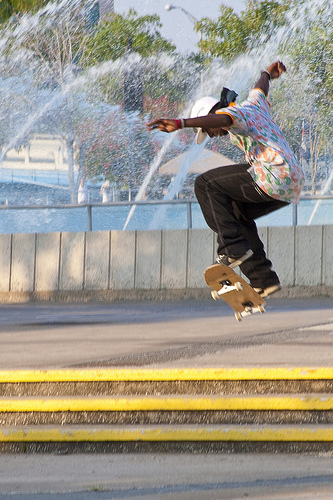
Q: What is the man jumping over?
A: Steps.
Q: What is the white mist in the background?
A: Water sprinkler.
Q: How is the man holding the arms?
A: Spread out in the air by his side.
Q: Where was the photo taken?
A: At a park.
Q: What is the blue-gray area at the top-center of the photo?
A: The sky.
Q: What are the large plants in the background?
A: Trees.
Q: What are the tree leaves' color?
A: Green.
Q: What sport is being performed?
A: Skateboarding.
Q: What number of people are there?
A: One.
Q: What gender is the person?
A: Male.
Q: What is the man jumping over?
A: Stairs.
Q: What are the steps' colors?
A: Yellow.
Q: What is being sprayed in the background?
A: Water.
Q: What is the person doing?
A: Skateboard tricks.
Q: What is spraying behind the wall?
A: Water.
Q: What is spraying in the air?
A: Water.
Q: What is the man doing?
A: Skateboarding.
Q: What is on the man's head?
A: Hat.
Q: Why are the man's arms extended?
A: Balance.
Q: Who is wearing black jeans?
A: The skater.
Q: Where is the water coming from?
A: The pool.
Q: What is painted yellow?
A: The steps.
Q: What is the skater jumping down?
A: The stairs.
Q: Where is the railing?
A: Behind the wall.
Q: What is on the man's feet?
A: Skateboard.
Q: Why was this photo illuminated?
A: Sunlight.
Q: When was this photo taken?
A: During the day.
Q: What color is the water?
A: Blue.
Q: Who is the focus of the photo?
A: The man.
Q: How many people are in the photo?
A: One.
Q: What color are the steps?
A: Yellow.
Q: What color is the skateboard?
A: Brown.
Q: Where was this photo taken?
A: At a skatepark.